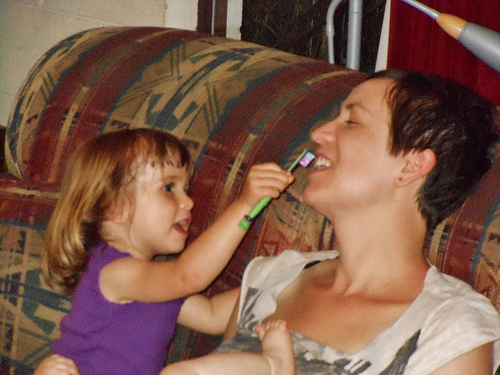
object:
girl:
[58, 138, 179, 372]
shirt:
[61, 247, 174, 374]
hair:
[78, 139, 106, 166]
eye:
[166, 187, 172, 192]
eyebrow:
[163, 175, 180, 182]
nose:
[183, 196, 191, 208]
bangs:
[153, 133, 182, 164]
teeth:
[183, 223, 186, 225]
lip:
[183, 232, 187, 239]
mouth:
[174, 217, 193, 240]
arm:
[114, 198, 275, 296]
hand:
[248, 163, 285, 194]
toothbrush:
[301, 154, 308, 164]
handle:
[246, 198, 271, 221]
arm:
[162, 283, 252, 326]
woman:
[293, 61, 499, 374]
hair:
[384, 59, 490, 193]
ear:
[107, 198, 125, 221]